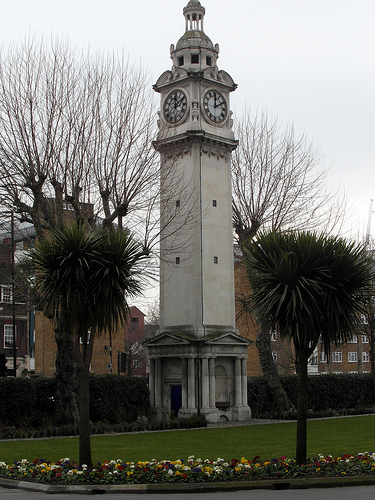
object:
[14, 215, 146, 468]
trees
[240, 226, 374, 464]
trees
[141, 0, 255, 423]
tower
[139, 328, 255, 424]
base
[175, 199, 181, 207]
windows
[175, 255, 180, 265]
windows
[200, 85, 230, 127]
clock face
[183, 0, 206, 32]
cupola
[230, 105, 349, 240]
branches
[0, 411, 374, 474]
grass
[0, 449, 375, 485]
flowers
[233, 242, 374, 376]
buildings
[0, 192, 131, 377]
buildings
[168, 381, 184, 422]
entrance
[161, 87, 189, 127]
clock face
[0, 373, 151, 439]
shrubs